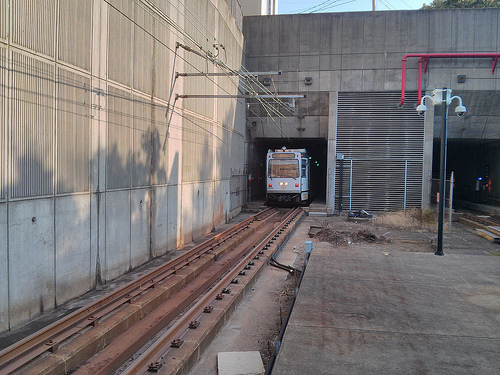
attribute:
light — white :
[414, 95, 433, 114]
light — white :
[450, 97, 467, 116]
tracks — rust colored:
[146, 255, 247, 347]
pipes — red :
[399, 45, 496, 102]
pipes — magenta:
[393, 51, 498, 105]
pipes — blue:
[337, 147, 415, 201]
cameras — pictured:
[408, 67, 493, 145]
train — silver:
[261, 137, 314, 212]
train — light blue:
[249, 130, 350, 211]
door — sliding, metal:
[335, 91, 424, 214]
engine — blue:
[266, 135, 310, 202]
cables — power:
[107, 0, 304, 125]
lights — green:
[308, 155, 324, 172]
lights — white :
[416, 89, 474, 123]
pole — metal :
[435, 81, 450, 253]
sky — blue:
[276, 0, 426, 10]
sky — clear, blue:
[291, 0, 411, 21]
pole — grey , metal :
[428, 115, 454, 265]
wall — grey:
[37, 32, 123, 186]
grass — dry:
[372, 204, 436, 230]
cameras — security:
[412, 82, 467, 120]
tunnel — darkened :
[430, 138, 498, 213]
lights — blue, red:
[476, 176, 496, 192]